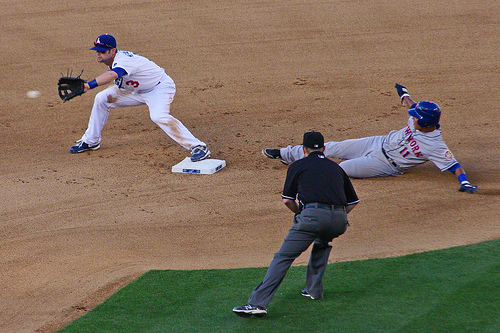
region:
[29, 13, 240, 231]
this is a person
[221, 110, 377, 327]
this is a person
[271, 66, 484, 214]
this is a person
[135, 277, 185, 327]
this is the grass carpet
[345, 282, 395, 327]
this is the grass carpet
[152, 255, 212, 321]
this is the grass carpet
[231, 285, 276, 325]
this is a shoe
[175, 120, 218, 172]
this is a shoe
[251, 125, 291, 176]
this is a shoe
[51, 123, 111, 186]
this is a shoe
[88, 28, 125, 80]
the head of a man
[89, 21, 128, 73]
the face of a man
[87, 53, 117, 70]
the chin of a man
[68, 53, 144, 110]
the arm of a man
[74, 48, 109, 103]
the wrist of a man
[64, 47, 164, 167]
the leg of a man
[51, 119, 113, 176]
the foot of a man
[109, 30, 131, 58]
the ear of a man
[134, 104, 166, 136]
the knee of a man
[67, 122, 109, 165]
a man wearing a shoe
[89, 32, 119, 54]
a blue cap on a man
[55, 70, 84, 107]
a black glove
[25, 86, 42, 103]
a white baseball in the air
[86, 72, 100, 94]
a blue wristband on a man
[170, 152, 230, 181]
a square white base under a foot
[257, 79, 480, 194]
a man sliding into base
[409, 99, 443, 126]
a blue helmet on a man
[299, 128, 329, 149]
a black cap on a man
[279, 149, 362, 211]
a black shirt on a man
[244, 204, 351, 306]
grey pants on a man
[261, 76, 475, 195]
Baseball player sliding to the plate.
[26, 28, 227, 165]
Baseball player catching the baseball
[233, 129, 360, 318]
Umpire watching the action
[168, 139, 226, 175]
Player's foot on the base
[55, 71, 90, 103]
Baseball mitt on player's hand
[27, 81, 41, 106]
Baseball in the area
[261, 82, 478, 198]
Baseball player on the ground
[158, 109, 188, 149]
Dirt on player's pants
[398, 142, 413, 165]
The number 11 on player's jersey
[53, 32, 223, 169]
base ball player in uniform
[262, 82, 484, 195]
base ball player in uniform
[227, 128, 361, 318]
umpire wearing a black shirt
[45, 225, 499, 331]
patch of dark green grass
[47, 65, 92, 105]
black leather catcher's mitt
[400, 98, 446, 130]
black plastic base ball helmet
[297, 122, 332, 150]
black base ball cap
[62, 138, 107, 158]
blue and white cleats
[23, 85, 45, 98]
blurry white base ball in motion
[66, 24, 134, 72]
fielder has blue hat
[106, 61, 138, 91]
red number on uniform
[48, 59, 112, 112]
fielder has black glove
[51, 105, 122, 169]
fielder has blue shoes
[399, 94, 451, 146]
runner has blue helmet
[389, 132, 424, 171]
blue and orange number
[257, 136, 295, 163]
runner has black shoes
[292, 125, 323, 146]
umpire has black hat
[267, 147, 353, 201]
umpire has black shirt